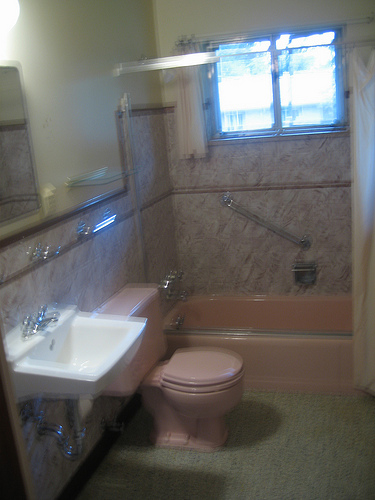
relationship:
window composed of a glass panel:
[207, 24, 346, 149] [213, 39, 273, 134]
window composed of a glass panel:
[207, 24, 346, 149] [279, 32, 335, 125]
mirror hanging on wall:
[1, 66, 46, 229] [31, 8, 109, 143]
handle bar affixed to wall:
[218, 193, 313, 254] [180, 195, 227, 292]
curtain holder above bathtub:
[113, 38, 373, 78] [165, 293, 351, 392]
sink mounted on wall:
[3, 304, 150, 402] [2, 285, 101, 303]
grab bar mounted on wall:
[218, 193, 313, 254] [180, 195, 227, 292]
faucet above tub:
[159, 272, 183, 304] [165, 293, 351, 392]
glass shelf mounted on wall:
[68, 169, 132, 191] [31, 8, 109, 143]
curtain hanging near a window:
[343, 50, 374, 401] [207, 24, 346, 149]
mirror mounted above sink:
[1, 66, 46, 229] [3, 304, 150, 402]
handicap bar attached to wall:
[218, 193, 313, 254] [180, 195, 227, 292]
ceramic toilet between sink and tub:
[161, 346, 245, 453] [2, 294, 348, 406]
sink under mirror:
[3, 304, 150, 402] [1, 66, 46, 229]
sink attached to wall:
[3, 304, 150, 402] [2, 285, 101, 303]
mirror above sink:
[1, 66, 46, 229] [3, 304, 150, 402]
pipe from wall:
[41, 418, 88, 462] [32, 444, 57, 498]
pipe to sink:
[41, 418, 88, 462] [3, 304, 150, 402]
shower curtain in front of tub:
[343, 50, 374, 401] [165, 293, 351, 392]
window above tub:
[207, 24, 346, 149] [165, 293, 351, 392]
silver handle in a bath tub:
[218, 193, 313, 254] [165, 293, 351, 392]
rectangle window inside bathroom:
[207, 24, 346, 149] [0, 1, 374, 500]